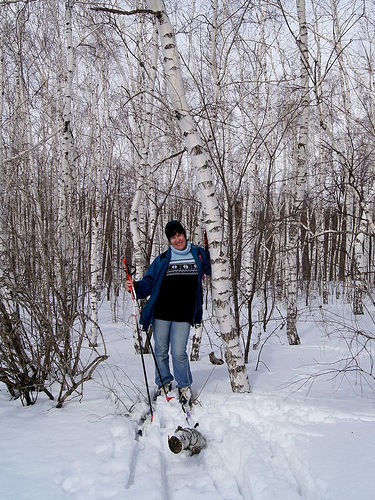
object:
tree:
[167, 423, 213, 464]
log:
[164, 421, 205, 457]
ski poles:
[118, 257, 153, 423]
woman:
[118, 215, 214, 405]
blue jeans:
[150, 318, 193, 393]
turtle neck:
[168, 243, 191, 257]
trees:
[280, 9, 311, 352]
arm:
[202, 248, 214, 275]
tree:
[239, 0, 267, 312]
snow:
[0, 401, 374, 498]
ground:
[9, 322, 373, 499]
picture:
[4, 4, 373, 494]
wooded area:
[2, 3, 374, 390]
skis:
[177, 391, 199, 441]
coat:
[129, 244, 213, 328]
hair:
[160, 217, 187, 240]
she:
[121, 217, 212, 405]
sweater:
[129, 244, 217, 324]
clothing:
[134, 243, 213, 390]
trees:
[84, 7, 103, 348]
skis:
[132, 383, 170, 438]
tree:
[259, 40, 279, 345]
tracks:
[122, 427, 171, 493]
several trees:
[1, 3, 363, 404]